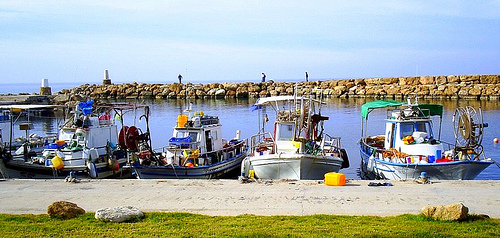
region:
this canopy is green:
[355, 95, 450, 122]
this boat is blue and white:
[144, 116, 229, 204]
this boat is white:
[241, 89, 351, 196]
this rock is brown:
[44, 188, 89, 224]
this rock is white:
[91, 199, 150, 228]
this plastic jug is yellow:
[318, 166, 350, 188]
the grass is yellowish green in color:
[165, 216, 220, 232]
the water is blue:
[331, 110, 351, 135]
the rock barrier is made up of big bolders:
[332, 70, 390, 95]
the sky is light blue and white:
[52, 13, 154, 41]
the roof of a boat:
[253, 87, 330, 114]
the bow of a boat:
[246, 148, 343, 182]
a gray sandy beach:
[0, 175, 499, 217]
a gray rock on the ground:
[91, 200, 149, 225]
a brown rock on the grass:
[417, 197, 472, 223]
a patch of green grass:
[1, 210, 498, 235]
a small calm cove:
[0, 93, 498, 176]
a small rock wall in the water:
[51, 73, 498, 108]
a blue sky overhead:
[0, 0, 499, 86]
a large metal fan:
[443, 97, 490, 154]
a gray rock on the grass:
[91, 203, 149, 228]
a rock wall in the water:
[55, 72, 499, 102]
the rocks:
[364, 75, 439, 94]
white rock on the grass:
[91, 204, 143, 224]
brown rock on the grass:
[423, 208, 465, 222]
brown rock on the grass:
[48, 199, 81, 217]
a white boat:
[253, 139, 328, 172]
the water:
[336, 96, 356, 128]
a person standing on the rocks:
[171, 71, 183, 82]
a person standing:
[258, 73, 268, 83]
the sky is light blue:
[182, 14, 301, 61]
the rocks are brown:
[372, 78, 450, 97]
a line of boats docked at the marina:
[16, 97, 488, 178]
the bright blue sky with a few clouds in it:
[5, 1, 495, 77]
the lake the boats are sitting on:
[17, 101, 492, 181]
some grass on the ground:
[6, 210, 496, 235]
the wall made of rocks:
[70, 73, 498, 98]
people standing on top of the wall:
[164, 72, 309, 80]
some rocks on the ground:
[53, 200, 145, 225]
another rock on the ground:
[415, 200, 463, 225]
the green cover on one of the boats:
[354, 96, 435, 116]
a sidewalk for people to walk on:
[11, 182, 494, 213]